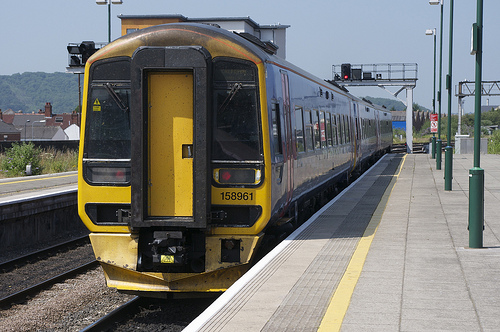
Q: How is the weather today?
A: It is cloudless.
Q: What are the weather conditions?
A: It is cloudless.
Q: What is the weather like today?
A: It is cloudless.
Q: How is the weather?
A: It is cloudless.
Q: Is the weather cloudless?
A: Yes, it is cloudless.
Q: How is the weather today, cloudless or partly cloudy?
A: It is cloudless.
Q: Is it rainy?
A: No, it is cloudless.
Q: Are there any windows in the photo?
A: Yes, there is a window.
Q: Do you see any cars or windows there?
A: Yes, there is a window.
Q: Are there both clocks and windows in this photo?
A: No, there is a window but no clocks.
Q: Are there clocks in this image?
A: No, there are no clocks.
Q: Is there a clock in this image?
A: No, there are no clocks.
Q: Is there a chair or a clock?
A: No, there are no clocks or chairs.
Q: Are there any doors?
A: Yes, there is a door.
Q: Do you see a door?
A: Yes, there is a door.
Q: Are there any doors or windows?
A: Yes, there is a door.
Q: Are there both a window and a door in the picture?
A: Yes, there are both a door and a window.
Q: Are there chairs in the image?
A: No, there are no chairs.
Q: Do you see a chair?
A: No, there are no chairs.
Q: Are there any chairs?
A: No, there are no chairs.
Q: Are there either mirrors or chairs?
A: No, there are no chairs or mirrors.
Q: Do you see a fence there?
A: No, there are no fences.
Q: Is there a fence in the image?
A: No, there are no fences.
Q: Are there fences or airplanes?
A: No, there are no fences or airplanes.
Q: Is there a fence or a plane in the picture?
A: No, there are no fences or airplanes.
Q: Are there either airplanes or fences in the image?
A: No, there are no fences or airplanes.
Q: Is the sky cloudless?
A: Yes, the sky is cloudless.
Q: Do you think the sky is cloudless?
A: Yes, the sky is cloudless.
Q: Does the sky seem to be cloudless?
A: Yes, the sky is cloudless.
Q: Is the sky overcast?
A: No, the sky is cloudless.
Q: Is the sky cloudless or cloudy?
A: The sky is cloudless.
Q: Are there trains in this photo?
A: Yes, there is a train.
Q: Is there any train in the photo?
A: Yes, there is a train.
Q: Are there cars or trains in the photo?
A: Yes, there is a train.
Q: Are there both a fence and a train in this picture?
A: No, there is a train but no fences.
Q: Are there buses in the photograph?
A: No, there are no buses.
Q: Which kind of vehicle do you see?
A: The vehicle is a train.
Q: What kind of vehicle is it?
A: The vehicle is a train.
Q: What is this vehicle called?
A: That is a train.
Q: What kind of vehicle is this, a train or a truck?
A: That is a train.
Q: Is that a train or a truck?
A: That is a train.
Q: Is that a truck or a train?
A: That is a train.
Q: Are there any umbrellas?
A: No, there are no umbrellas.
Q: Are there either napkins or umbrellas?
A: No, there are no umbrellas or napkins.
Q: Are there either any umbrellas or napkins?
A: No, there are no umbrellas or napkins.